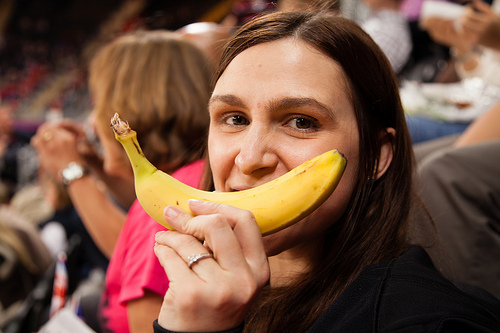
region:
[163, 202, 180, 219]
clean pink finger nail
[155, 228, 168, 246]
clean pink finger nail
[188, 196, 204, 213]
clean pink finger nail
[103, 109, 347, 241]
ripe yellow colored banana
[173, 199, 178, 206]
brown spot on banana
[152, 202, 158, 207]
brown spot on banana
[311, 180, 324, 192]
brown spot on banana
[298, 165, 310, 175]
brown spot on banana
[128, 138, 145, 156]
brown spot on banana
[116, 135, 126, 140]
brown spot on banana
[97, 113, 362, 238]
a ripe yellow banana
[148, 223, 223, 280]
finger with ring on it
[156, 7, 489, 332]
woman with brown eyes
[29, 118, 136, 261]
watch on an arm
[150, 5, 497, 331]
woman with dark brown hair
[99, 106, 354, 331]
banana being held with hand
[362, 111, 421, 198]
ear poking through hair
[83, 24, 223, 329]
woman wearing pink shirt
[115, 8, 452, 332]
straight brown hair on woman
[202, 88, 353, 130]
dark brown eyebrows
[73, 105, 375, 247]
The banana is ripe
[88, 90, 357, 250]
The banana is yellow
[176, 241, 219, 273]
This is an engagement rint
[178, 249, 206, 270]
The ring has a diamond center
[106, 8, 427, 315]
The woman is holding a banana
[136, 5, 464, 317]
The woman has dark hair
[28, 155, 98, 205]
This person is wearing a watch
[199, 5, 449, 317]
The woman's hair is brown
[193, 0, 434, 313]
The woman's hair is straight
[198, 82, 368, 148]
The woman has dark brown eyes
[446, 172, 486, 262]
a woman is wearing grey pants.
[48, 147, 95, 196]
a woman is wearing a watch.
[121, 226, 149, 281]
a woman is wearing a pink shirt.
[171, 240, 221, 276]
a woman is wearing a silver ring.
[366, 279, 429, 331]
a woman is wearing a black shirt.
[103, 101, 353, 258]
a woman is holding a banana.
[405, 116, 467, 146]
a man is wearing blue jeans.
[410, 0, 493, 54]
a man is holding a white cup.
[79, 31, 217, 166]
a woman is wearing a short brown hair style.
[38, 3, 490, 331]
a woman is going to eat the banana.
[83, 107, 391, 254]
a yellow banana in hand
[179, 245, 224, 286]
an engagement ring on finger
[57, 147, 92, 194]
a watch on a wrist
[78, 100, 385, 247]
using a banana as a smile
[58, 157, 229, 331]
pink shirt of a woman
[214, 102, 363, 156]
woman has brown eyes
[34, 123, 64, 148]
wedding ring on man's hand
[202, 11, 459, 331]
long dark brown hair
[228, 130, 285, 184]
a pointy nose on woman's face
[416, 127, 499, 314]
brown pants on a leg